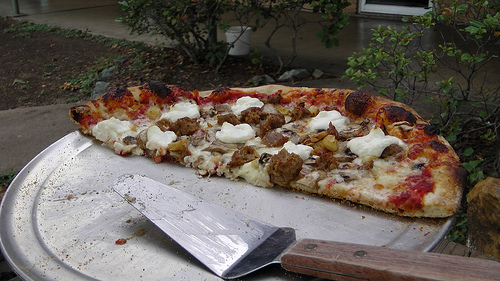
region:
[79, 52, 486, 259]
a pizza on a pan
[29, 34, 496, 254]
a pizza on a silver pan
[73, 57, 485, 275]
a baked pizza on a pan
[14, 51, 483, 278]
a baked pizza on a silver pan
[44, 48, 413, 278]
a cooked pizza on a pan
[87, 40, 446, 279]
a cooked pizza on a silver pan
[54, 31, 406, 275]
a half of a pizza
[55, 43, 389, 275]
a half of a baked pizza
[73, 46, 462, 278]
half of a cooked pizza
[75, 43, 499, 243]
pizza that has been cooked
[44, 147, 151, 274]
Metal pizza tray on table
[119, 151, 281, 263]
Metal spatula on a pizza tray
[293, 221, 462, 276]
Wood handle of a spatula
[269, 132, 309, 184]
Sausage on a pizza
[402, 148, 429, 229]
Tomato sauce on a pizza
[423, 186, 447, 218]
Edge of a pizza crust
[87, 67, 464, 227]
Pizza on a pizza tray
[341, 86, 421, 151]
Burnt edge of a pizza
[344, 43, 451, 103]
Plant in the background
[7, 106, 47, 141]
Wood table outside in a yard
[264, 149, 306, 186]
meat topping on pizza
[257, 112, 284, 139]
meat topping on pizza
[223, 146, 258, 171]
meat topping on pizza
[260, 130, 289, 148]
meat topping on pizza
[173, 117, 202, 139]
meat topping on pizza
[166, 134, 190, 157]
meat topping on pizza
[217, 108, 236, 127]
meat topping on pizza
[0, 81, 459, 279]
half pizza on meatal pan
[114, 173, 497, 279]
pizza spatula with wooden handle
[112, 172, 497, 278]
metal pizza spatula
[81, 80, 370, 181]
pizza on a metal baking pan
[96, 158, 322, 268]
metal pie server with wooden handle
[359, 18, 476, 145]
bush behind the pizza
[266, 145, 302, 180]
sausage on the pizza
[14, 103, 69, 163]
sidewalk behind the pizza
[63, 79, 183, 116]
bubbly crust on the pizza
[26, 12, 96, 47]
weeds growing at the edge of the sidewalk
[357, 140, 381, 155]
melted cheese on the pizza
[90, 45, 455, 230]
half of a pizza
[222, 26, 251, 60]
white bucket behind the bush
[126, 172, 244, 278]
Silver spatula on pizza tray.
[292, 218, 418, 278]
Wood handle on spatula.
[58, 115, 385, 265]
Silver tray under pizza.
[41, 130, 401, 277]
Silver tray is round.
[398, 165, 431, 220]
Red sauce on pizza.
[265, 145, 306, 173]
Brown sausage on top of pizza.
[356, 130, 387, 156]
White cheese melted on pizza.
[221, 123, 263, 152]
White cheese melted on pizza.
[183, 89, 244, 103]
Red sauce on top of pizza.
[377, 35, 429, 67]
Green leaves on plant behind pizza.